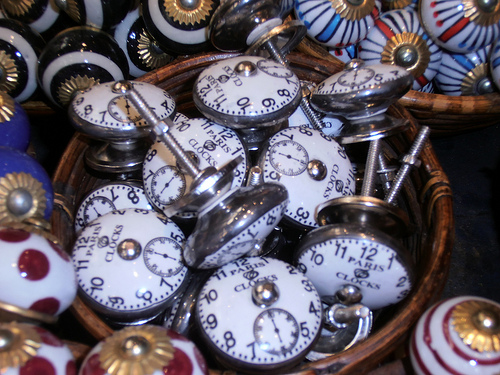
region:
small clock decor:
[195, 50, 302, 122]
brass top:
[446, 294, 498, 356]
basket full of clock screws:
[57, 57, 451, 350]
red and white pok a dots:
[0, 229, 68, 322]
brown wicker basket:
[420, 165, 457, 296]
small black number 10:
[201, 285, 220, 305]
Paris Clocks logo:
[334, 253, 386, 295]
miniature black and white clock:
[75, 207, 191, 303]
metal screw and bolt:
[375, 121, 432, 203]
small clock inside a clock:
[251, 305, 302, 357]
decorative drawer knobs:
[15, 14, 485, 363]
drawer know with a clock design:
[196, 249, 329, 367]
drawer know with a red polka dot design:
[3, 213, 80, 332]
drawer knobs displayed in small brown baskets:
[77, 25, 484, 351]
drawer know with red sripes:
[413, 303, 498, 370]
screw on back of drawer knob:
[115, 85, 235, 221]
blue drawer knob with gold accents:
[3, 148, 53, 226]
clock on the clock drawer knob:
[253, 308, 310, 350]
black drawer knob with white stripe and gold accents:
[43, 29, 129, 108]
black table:
[454, 171, 499, 286]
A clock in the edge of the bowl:
[194, 254, 326, 374]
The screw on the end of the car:
[126, 88, 228, 191]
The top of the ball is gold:
[92, 320, 172, 373]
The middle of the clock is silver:
[115, 232, 147, 265]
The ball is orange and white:
[361, 10, 451, 92]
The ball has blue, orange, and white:
[295, 0, 381, 49]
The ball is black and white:
[34, 18, 135, 109]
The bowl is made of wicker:
[38, 40, 458, 373]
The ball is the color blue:
[1, 143, 58, 230]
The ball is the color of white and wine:
[0, 220, 72, 324]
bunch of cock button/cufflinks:
[46, 18, 460, 365]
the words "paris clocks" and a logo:
[229, 265, 289, 295]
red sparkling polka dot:
[13, 244, 58, 284]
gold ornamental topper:
[1, 180, 54, 220]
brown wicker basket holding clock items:
[38, 37, 457, 370]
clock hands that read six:
[264, 313, 293, 353]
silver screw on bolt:
[401, 150, 421, 172]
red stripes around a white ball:
[421, 308, 493, 371]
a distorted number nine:
[103, 290, 130, 307]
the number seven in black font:
[244, 340, 260, 360]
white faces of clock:
[77, 49, 370, 351]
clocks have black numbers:
[189, 261, 318, 353]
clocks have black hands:
[226, 267, 304, 357]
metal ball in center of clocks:
[252, 277, 281, 310]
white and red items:
[375, 10, 445, 77]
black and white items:
[35, 20, 123, 91]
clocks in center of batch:
[65, 51, 407, 351]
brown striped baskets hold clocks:
[390, 79, 478, 227]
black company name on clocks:
[90, 230, 135, 270]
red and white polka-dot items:
[8, 222, 78, 320]